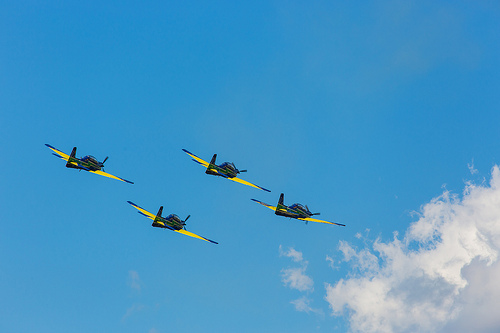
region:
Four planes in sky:
[42, 112, 354, 255]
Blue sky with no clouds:
[133, 37, 242, 91]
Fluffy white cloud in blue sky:
[369, 178, 474, 302]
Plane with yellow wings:
[120, 189, 223, 251]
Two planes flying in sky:
[40, 135, 292, 193]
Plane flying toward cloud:
[259, 180, 399, 280]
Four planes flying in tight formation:
[31, 108, 365, 251]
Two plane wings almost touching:
[245, 175, 281, 219]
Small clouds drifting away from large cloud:
[271, 240, 382, 314]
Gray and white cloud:
[419, 257, 489, 318]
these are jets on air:
[36, 140, 329, 270]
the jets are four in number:
[19, 140, 340, 265]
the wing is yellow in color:
[236, 178, 266, 193]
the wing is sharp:
[177, 229, 215, 244]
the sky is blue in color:
[3, 0, 493, 112]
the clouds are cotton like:
[368, 203, 495, 327]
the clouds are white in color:
[389, 246, 496, 323]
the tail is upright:
[153, 209, 164, 221]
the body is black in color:
[221, 163, 231, 169]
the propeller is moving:
[240, 167, 250, 172]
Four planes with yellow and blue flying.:
[42, 138, 346, 259]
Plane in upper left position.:
[44, 140, 135, 189]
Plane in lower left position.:
[127, 203, 221, 247]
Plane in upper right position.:
[181, 144, 268, 194]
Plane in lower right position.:
[249, 191, 347, 230]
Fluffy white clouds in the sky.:
[280, 161, 497, 332]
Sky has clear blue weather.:
[94, 16, 473, 138]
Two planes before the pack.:
[180, 143, 348, 230]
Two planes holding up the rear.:
[33, 141, 218, 252]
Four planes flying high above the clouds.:
[26, 143, 347, 253]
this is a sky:
[21, 0, 496, 90]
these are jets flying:
[31, 133, 355, 253]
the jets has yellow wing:
[176, 233, 207, 240]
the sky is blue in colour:
[8, 15, 477, 141]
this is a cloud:
[283, 228, 498, 330]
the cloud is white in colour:
[328, 231, 494, 327]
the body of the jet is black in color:
[66, 146, 104, 176]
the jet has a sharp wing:
[112, 175, 138, 190]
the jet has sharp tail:
[148, 205, 166, 230]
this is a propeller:
[183, 215, 190, 223]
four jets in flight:
[40, 121, 345, 253]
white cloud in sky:
[378, 184, 480, 269]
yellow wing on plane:
[180, 225, 212, 244]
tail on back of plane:
[60, 145, 84, 177]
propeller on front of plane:
[180, 207, 195, 229]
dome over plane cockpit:
[84, 148, 101, 165]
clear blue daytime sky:
[248, 39, 410, 119]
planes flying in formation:
[36, 123, 361, 250]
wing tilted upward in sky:
[171, 140, 208, 172]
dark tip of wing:
[247, 185, 277, 195]